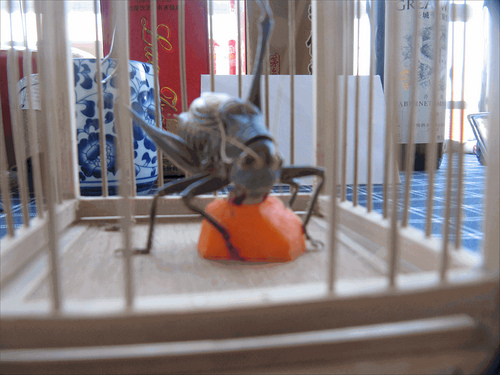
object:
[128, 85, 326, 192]
insect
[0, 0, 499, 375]
cage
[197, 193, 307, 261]
carrot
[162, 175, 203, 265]
legs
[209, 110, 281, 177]
antenna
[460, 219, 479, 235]
tile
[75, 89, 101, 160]
mug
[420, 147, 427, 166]
wine bottle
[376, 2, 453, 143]
white label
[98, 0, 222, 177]
box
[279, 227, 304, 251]
edge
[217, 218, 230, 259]
hand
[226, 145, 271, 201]
face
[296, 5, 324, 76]
gold symbols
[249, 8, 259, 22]
wall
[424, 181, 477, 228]
floor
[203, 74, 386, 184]
white board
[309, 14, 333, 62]
white spindles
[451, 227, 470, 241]
tablecloth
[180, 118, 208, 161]
wings